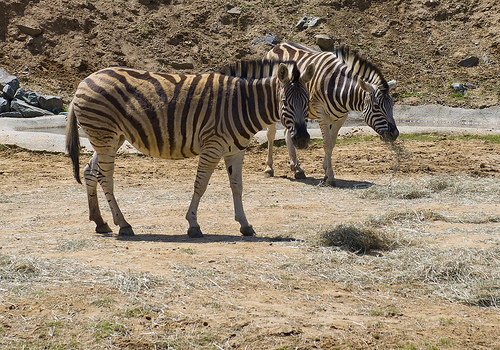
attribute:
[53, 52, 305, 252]
zebra — stripe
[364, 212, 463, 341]
grass — dead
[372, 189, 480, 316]
grass — dead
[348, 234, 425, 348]
grass — dead